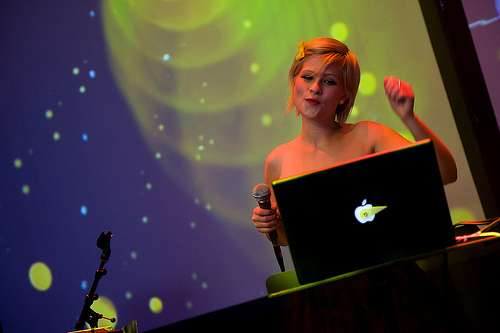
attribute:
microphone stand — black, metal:
[69, 225, 112, 331]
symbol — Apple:
[353, 198, 376, 223]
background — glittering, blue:
[3, 2, 485, 326]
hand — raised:
[377, 71, 418, 120]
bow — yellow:
[295, 39, 307, 60]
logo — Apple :
[349, 196, 386, 229]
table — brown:
[164, 252, 499, 327]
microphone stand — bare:
[77, 227, 123, 332]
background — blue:
[55, 82, 196, 209]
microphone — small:
[245, 175, 290, 275]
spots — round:
[80, 206, 89, 213]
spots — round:
[82, 136, 89, 141]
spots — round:
[46, 111, 52, 117]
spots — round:
[147, 184, 152, 189]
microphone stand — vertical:
[75, 232, 125, 331]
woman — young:
[248, 32, 462, 278]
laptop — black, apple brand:
[271, 140, 458, 284]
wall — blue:
[7, 13, 60, 85]